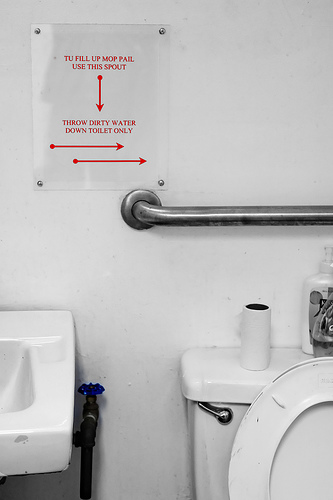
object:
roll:
[236, 303, 271, 371]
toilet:
[179, 347, 314, 500]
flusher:
[198, 402, 234, 425]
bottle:
[309, 291, 323, 345]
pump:
[324, 245, 333, 264]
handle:
[77, 382, 105, 396]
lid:
[181, 347, 314, 404]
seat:
[228, 355, 333, 500]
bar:
[121, 189, 333, 231]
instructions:
[49, 55, 147, 165]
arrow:
[50, 142, 124, 150]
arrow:
[73, 157, 147, 165]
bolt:
[34, 27, 41, 35]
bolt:
[159, 27, 166, 35]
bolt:
[158, 179, 164, 186]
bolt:
[37, 181, 43, 188]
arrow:
[96, 75, 105, 112]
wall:
[0, 0, 333, 500]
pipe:
[72, 417, 98, 500]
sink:
[0, 310, 75, 477]